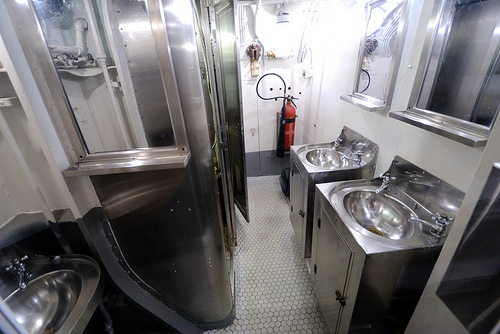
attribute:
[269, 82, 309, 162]
fire extinguisher — red, long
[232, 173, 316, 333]
floor — white, tessellation-patterned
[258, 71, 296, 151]
extingusher — red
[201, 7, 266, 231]
shower — door, narrow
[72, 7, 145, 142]
pipe — white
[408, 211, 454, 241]
faucet — shiny, metal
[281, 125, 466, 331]
steel sinks — stainless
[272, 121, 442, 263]
sinks — silver, double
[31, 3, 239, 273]
shower — Tiny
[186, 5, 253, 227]
door — stainless steel, open, rectangular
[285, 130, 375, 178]
sink — stainless steel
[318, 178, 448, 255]
sink — stainless steel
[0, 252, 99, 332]
sink — stainless steel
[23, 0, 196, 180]
mirror — left-side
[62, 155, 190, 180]
windowsill — stainless steel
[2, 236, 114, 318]
sink — corner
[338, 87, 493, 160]
shelves — little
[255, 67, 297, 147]
extinguisher hose — thin, black, fire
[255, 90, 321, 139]
extinguisher — fire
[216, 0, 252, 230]
door — glass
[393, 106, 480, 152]
ledge — stainless steel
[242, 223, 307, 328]
floor — narrow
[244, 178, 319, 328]
floor — honeycomb patterned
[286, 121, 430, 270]
two sinks — Silver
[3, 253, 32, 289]
faucet — left-side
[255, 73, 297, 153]
extinguisher — red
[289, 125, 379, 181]
sinks — free-standing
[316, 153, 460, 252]
sinks — free-standing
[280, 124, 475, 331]
sinks — stainless, steel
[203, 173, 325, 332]
floor tile — white, honeycomb, bathroom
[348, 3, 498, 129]
mirrors — stainless steel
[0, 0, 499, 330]
bathroom — compact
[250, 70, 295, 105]
hose — black